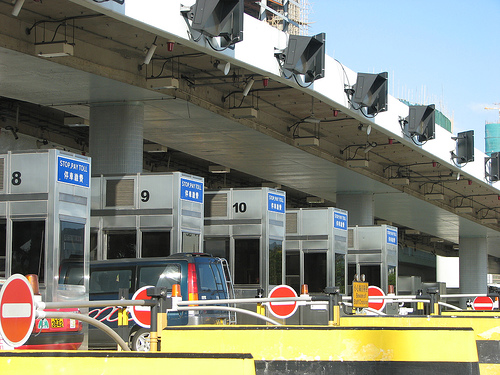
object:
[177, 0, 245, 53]
speaker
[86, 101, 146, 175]
pillar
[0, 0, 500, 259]
roof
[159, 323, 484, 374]
barrier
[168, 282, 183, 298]
light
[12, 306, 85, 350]
car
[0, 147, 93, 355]
tollbooth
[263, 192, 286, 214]
sign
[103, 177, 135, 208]
vent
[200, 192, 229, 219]
vent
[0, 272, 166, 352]
gates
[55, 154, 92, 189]
sign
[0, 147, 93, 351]
stand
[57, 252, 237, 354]
van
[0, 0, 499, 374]
parking lot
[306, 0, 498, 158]
sky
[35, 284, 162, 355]
lanes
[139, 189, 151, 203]
number 9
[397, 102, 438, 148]
light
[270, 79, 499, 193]
wall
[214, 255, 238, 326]
ladder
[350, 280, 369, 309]
sign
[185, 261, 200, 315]
light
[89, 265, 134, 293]
window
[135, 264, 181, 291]
window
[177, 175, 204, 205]
sign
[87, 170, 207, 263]
booth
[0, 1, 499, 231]
area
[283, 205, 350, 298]
booth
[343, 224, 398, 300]
booth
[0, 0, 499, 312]
building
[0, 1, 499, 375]
scene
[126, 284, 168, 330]
sign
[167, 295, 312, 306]
pole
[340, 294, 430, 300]
pole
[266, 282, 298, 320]
sign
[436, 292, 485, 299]
pole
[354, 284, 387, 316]
sign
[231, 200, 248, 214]
number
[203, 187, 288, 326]
station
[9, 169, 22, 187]
number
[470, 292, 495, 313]
sign